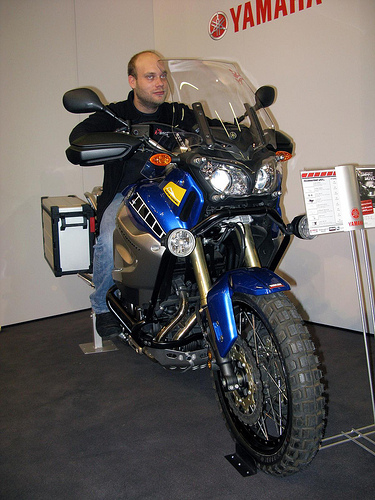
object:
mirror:
[61, 87, 103, 113]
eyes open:
[160, 74, 167, 79]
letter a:
[242, 1, 255, 30]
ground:
[0, 432, 104, 496]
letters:
[230, 5, 242, 34]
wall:
[292, 3, 373, 115]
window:
[163, 56, 277, 138]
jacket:
[69, 89, 224, 238]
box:
[41, 195, 94, 276]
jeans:
[88, 177, 137, 317]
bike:
[41, 59, 325, 478]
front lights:
[208, 165, 248, 194]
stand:
[298, 165, 373, 410]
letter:
[255, 0, 271, 25]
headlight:
[252, 158, 282, 192]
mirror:
[255, 86, 275, 109]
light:
[150, 153, 172, 166]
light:
[167, 227, 196, 258]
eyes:
[146, 74, 153, 80]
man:
[67, 48, 289, 341]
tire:
[208, 272, 325, 482]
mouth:
[153, 90, 164, 95]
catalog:
[299, 167, 374, 235]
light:
[297, 214, 318, 240]